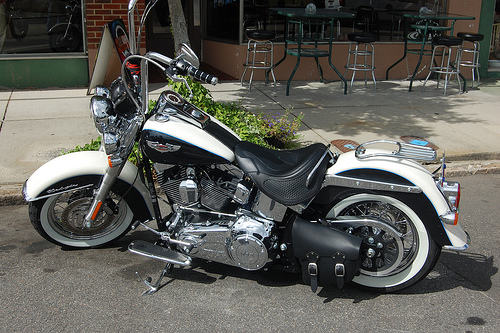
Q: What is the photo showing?
A: It is showing a street.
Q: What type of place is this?
A: It is a street.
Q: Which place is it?
A: It is a street.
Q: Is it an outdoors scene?
A: Yes, it is outdoors.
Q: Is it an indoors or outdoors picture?
A: It is outdoors.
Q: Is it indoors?
A: No, it is outdoors.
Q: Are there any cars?
A: No, there are no cars.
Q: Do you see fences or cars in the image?
A: No, there are no cars or fences.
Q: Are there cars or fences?
A: No, there are no cars or fences.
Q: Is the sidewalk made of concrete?
A: Yes, the sidewalk is made of concrete.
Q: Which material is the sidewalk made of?
A: The sidewalk is made of concrete.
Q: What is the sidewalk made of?
A: The sidewalk is made of concrete.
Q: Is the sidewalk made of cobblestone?
A: No, the sidewalk is made of concrete.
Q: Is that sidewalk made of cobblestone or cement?
A: The sidewalk is made of cement.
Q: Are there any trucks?
A: No, there are no trucks.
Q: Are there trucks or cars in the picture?
A: No, there are no trucks or cars.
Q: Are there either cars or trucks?
A: No, there are no trucks or cars.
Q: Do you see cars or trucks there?
A: No, there are no trucks or cars.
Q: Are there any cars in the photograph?
A: No, there are no cars.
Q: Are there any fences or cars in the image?
A: No, there are no cars or fences.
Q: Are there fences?
A: No, there are no fences.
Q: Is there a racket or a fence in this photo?
A: No, there are no fences or rackets.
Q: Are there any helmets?
A: No, there are no helmets.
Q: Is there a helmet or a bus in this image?
A: No, there are no helmets or buses.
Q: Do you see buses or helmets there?
A: No, there are no helmets or buses.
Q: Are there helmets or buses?
A: No, there are no helmets or buses.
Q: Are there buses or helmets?
A: No, there are no helmets or buses.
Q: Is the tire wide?
A: Yes, the tire is wide.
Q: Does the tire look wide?
A: Yes, the tire is wide.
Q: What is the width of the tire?
A: The tire is wide.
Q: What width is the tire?
A: The tire is wide.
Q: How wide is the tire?
A: The tire is wide.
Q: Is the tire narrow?
A: No, the tire is wide.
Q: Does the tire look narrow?
A: No, the tire is wide.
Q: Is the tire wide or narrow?
A: The tire is wide.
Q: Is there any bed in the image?
A: No, there are no beds.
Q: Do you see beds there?
A: No, there are no beds.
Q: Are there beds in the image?
A: No, there are no beds.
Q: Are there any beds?
A: No, there are no beds.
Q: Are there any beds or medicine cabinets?
A: No, there are no beds or medicine cabinets.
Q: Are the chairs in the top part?
A: Yes, the chairs are in the top of the image.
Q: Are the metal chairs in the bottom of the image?
A: No, the chairs are in the top of the image.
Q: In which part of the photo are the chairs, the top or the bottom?
A: The chairs are in the top of the image.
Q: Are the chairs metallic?
A: Yes, the chairs are metallic.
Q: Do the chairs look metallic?
A: Yes, the chairs are metallic.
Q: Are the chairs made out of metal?
A: Yes, the chairs are made of metal.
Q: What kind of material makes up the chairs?
A: The chairs are made of metal.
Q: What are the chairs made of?
A: The chairs are made of metal.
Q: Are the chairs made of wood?
A: No, the chairs are made of metal.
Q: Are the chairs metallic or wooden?
A: The chairs are metallic.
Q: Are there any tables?
A: Yes, there is a table.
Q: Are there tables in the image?
A: Yes, there is a table.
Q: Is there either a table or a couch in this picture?
A: Yes, there is a table.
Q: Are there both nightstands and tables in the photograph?
A: No, there is a table but no nightstands.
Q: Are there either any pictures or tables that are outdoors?
A: Yes, the table is outdoors.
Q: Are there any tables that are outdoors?
A: Yes, there is a table that is outdoors.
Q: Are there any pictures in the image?
A: No, there are no pictures.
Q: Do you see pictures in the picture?
A: No, there are no pictures.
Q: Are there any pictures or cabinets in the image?
A: No, there are no pictures or cabinets.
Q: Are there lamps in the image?
A: No, there are no lamps.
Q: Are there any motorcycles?
A: Yes, there is a motorcycle.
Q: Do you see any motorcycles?
A: Yes, there is a motorcycle.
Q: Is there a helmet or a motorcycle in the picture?
A: Yes, there is a motorcycle.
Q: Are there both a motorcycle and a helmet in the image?
A: No, there is a motorcycle but no helmets.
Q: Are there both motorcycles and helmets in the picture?
A: No, there is a motorcycle but no helmets.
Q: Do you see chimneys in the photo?
A: No, there are no chimneys.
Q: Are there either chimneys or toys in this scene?
A: No, there are no chimneys or toys.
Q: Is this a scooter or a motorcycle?
A: This is a motorcycle.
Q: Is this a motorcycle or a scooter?
A: This is a motorcycle.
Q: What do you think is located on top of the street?
A: The motorbike is on top of the street.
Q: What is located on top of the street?
A: The motorbike is on top of the street.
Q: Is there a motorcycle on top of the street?
A: Yes, there is a motorcycle on top of the street.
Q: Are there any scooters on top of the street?
A: No, there is a motorcycle on top of the street.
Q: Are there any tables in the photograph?
A: Yes, there is a table.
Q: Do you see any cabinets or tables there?
A: Yes, there is a table.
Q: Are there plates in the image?
A: No, there are no plates.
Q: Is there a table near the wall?
A: Yes, there is a table near the wall.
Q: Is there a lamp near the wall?
A: No, there is a table near the wall.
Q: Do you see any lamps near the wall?
A: No, there is a table near the wall.